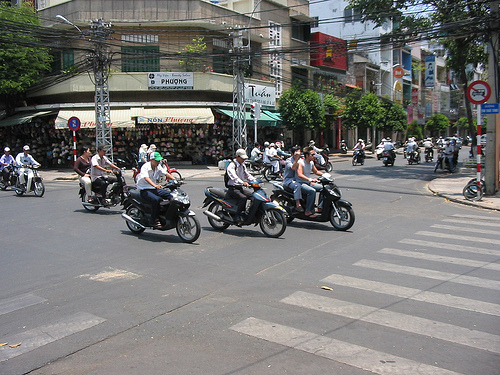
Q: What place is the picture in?
A: It is at the street.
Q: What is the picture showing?
A: It is showing a street.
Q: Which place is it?
A: It is a street.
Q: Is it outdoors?
A: Yes, it is outdoors.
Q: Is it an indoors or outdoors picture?
A: It is outdoors.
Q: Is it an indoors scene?
A: No, it is outdoors.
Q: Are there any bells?
A: No, there are no bells.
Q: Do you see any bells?
A: No, there are no bells.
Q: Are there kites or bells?
A: No, there are no bells or kites.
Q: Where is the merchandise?
A: The merchandise is in the store.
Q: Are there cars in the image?
A: No, there are no cars.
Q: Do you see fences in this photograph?
A: No, there are no fences.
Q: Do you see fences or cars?
A: No, there are no fences or cars.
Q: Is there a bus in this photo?
A: No, there are no buses.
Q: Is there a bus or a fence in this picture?
A: No, there are no buses or fences.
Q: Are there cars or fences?
A: No, there are no cars or fences.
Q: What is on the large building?
A: The sign is on the building.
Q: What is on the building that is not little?
A: The sign is on the building.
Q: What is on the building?
A: The sign is on the building.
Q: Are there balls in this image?
A: No, there are no balls.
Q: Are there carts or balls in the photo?
A: No, there are no balls or carts.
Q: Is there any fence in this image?
A: No, there are no fences.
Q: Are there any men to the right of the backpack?
A: Yes, there is a man to the right of the backpack.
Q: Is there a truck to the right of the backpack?
A: No, there is a man to the right of the backpack.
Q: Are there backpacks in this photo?
A: Yes, there is a backpack.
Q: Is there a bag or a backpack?
A: Yes, there is a backpack.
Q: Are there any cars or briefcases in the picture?
A: No, there are no cars or briefcases.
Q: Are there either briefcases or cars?
A: No, there are no cars or briefcases.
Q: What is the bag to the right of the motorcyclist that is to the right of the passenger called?
A: The bag is a backpack.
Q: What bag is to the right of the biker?
A: The bag is a backpack.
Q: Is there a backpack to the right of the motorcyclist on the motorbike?
A: Yes, there is a backpack to the right of the biker.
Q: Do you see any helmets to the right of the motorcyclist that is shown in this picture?
A: No, there is a backpack to the right of the motorcyclist.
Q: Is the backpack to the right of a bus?
A: No, the backpack is to the right of the motorcyclist.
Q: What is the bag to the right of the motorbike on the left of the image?
A: The bag is a backpack.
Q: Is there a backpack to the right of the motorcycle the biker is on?
A: Yes, there is a backpack to the right of the motorbike.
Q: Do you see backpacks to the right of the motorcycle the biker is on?
A: Yes, there is a backpack to the right of the motorbike.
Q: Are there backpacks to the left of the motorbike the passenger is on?
A: No, the backpack is to the right of the motorbike.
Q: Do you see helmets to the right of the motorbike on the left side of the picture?
A: No, there is a backpack to the right of the motorbike.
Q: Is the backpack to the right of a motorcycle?
A: Yes, the backpack is to the right of a motorcycle.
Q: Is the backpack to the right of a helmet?
A: No, the backpack is to the right of a motorcycle.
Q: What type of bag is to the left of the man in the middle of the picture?
A: The bag is a backpack.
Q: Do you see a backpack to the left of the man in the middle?
A: Yes, there is a backpack to the left of the man.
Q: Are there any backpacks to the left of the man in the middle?
A: Yes, there is a backpack to the left of the man.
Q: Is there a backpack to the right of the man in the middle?
A: No, the backpack is to the left of the man.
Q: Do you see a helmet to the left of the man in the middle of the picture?
A: No, there is a backpack to the left of the man.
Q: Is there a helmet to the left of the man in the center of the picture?
A: No, there is a backpack to the left of the man.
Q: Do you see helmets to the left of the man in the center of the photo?
A: No, there is a backpack to the left of the man.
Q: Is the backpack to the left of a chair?
A: No, the backpack is to the left of the man.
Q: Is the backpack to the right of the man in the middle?
A: No, the backpack is to the left of the man.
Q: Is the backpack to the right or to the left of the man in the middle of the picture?
A: The backpack is to the left of the man.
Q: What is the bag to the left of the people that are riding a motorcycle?
A: The bag is a backpack.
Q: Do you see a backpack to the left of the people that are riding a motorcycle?
A: Yes, there is a backpack to the left of the people.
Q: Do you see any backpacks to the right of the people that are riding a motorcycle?
A: No, the backpack is to the left of the people.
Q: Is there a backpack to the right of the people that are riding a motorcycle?
A: No, the backpack is to the left of the people.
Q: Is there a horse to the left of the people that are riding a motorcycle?
A: No, there is a backpack to the left of the people.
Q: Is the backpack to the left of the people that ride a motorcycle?
A: Yes, the backpack is to the left of the people.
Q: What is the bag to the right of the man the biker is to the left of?
A: The bag is a backpack.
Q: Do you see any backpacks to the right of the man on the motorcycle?
A: Yes, there is a backpack to the right of the man.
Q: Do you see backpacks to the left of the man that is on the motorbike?
A: No, the backpack is to the right of the man.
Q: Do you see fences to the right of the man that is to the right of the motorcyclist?
A: No, there is a backpack to the right of the man.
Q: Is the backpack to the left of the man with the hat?
A: No, the backpack is to the right of the man.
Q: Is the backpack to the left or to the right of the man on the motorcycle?
A: The backpack is to the right of the man.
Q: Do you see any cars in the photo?
A: No, there are no cars.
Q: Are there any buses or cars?
A: No, there are no cars or buses.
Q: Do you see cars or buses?
A: No, there are no cars or buses.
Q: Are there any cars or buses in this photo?
A: No, there are no cars or buses.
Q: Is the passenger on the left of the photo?
A: Yes, the passenger is on the left of the image.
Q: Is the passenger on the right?
A: No, the passenger is on the left of the image.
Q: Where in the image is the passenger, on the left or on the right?
A: The passenger is on the left of the image.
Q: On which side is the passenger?
A: The passenger is on the left of the image.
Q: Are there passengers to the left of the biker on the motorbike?
A: Yes, there is a passenger to the left of the motorcyclist.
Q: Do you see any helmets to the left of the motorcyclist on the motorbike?
A: No, there is a passenger to the left of the motorcyclist.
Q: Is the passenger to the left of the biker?
A: Yes, the passenger is to the left of the biker.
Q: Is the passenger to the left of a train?
A: No, the passenger is to the left of the biker.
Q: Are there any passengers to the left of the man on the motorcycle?
A: Yes, there is a passenger to the left of the man.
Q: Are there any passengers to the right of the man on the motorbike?
A: No, the passenger is to the left of the man.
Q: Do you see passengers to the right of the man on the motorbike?
A: No, the passenger is to the left of the man.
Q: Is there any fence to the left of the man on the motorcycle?
A: No, there is a passenger to the left of the man.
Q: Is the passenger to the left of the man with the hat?
A: Yes, the passenger is to the left of the man.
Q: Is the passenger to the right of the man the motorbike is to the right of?
A: No, the passenger is to the left of the man.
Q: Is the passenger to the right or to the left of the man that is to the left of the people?
A: The passenger is to the left of the man.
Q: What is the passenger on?
A: The passenger is on the motorcycle.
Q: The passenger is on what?
A: The passenger is on the motorcycle.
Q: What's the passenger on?
A: The passenger is on the motorcycle.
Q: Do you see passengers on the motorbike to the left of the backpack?
A: Yes, there is a passenger on the motorcycle.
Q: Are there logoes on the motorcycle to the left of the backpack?
A: No, there is a passenger on the motorcycle.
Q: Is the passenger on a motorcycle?
A: Yes, the passenger is on a motorcycle.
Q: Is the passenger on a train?
A: No, the passenger is on a motorcycle.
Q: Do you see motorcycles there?
A: Yes, there is a motorcycle.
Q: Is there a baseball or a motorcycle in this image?
A: Yes, there is a motorcycle.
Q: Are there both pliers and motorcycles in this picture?
A: No, there is a motorcycle but no pliers.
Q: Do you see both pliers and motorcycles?
A: No, there is a motorcycle but no pliers.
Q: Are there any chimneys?
A: No, there are no chimneys.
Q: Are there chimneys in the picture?
A: No, there are no chimneys.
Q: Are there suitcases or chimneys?
A: No, there are no chimneys or suitcases.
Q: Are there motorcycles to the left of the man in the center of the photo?
A: Yes, there is a motorcycle to the left of the man.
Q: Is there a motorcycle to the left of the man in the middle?
A: Yes, there is a motorcycle to the left of the man.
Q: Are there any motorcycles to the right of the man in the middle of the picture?
A: No, the motorcycle is to the left of the man.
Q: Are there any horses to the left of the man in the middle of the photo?
A: No, there is a motorcycle to the left of the man.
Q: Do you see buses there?
A: No, there are no buses.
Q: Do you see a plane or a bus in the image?
A: No, there are no buses or airplanes.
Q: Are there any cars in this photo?
A: No, there are no cars.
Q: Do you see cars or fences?
A: No, there are no cars or fences.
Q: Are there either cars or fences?
A: No, there are no cars or fences.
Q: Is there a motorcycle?
A: Yes, there is a motorcycle.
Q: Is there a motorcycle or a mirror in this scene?
A: Yes, there is a motorcycle.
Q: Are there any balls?
A: No, there are no balls.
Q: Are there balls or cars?
A: No, there are no balls or cars.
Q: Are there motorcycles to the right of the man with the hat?
A: Yes, there is a motorcycle to the right of the man.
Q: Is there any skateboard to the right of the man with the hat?
A: No, there is a motorcycle to the right of the man.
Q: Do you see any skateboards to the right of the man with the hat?
A: No, there is a motorcycle to the right of the man.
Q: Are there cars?
A: No, there are no cars.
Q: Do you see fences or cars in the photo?
A: No, there are no cars or fences.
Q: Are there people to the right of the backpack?
A: Yes, there are people to the right of the backpack.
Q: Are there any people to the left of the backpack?
A: No, the people are to the right of the backpack.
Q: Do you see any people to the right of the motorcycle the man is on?
A: Yes, there are people to the right of the motorbike.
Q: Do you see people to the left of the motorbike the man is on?
A: No, the people are to the right of the motorbike.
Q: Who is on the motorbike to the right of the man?
A: The people are on the motorcycle.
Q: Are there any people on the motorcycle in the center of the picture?
A: Yes, there are people on the motorcycle.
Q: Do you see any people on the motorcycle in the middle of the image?
A: Yes, there are people on the motorcycle.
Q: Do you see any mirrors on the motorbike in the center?
A: No, there are people on the motorcycle.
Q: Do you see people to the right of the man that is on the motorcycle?
A: Yes, there are people to the right of the man.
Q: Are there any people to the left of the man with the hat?
A: No, the people are to the right of the man.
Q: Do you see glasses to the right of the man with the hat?
A: No, there are people to the right of the man.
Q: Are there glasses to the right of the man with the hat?
A: No, there are people to the right of the man.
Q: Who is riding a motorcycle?
A: The people are riding a motorcycle.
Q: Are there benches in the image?
A: No, there are no benches.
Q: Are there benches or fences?
A: No, there are no benches or fences.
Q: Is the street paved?
A: Yes, the street is paved.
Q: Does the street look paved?
A: Yes, the street is paved.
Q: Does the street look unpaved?
A: No, the street is paved.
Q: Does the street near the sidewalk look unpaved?
A: No, the street is paved.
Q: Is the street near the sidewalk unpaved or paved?
A: The street is paved.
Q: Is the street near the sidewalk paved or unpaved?
A: The street is paved.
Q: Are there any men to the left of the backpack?
A: Yes, there is a man to the left of the backpack.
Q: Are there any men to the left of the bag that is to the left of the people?
A: Yes, there is a man to the left of the backpack.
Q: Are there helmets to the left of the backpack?
A: No, there is a man to the left of the backpack.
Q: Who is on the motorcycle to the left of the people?
A: The man is on the motorbike.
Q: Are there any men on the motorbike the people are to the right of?
A: Yes, there is a man on the motorbike.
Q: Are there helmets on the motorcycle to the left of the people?
A: No, there is a man on the motorbike.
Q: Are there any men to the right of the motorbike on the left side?
A: Yes, there is a man to the right of the motorcycle.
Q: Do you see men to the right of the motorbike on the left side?
A: Yes, there is a man to the right of the motorcycle.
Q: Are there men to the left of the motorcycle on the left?
A: No, the man is to the right of the motorcycle.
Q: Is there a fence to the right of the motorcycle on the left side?
A: No, there is a man to the right of the motorbike.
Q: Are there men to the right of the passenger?
A: Yes, there is a man to the right of the passenger.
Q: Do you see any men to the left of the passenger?
A: No, the man is to the right of the passenger.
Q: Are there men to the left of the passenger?
A: No, the man is to the right of the passenger.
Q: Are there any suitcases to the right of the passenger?
A: No, there is a man to the right of the passenger.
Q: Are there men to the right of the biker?
A: Yes, there is a man to the right of the biker.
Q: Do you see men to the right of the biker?
A: Yes, there is a man to the right of the biker.